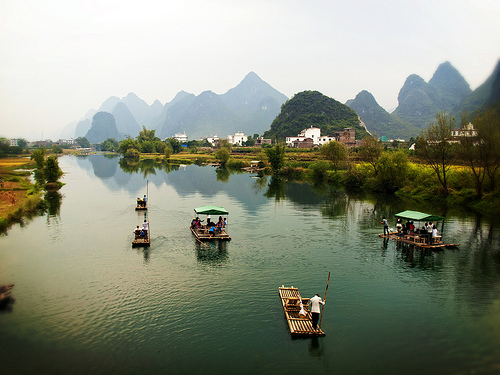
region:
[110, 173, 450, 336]
rafts on the river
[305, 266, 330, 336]
a person standing on a wooden raft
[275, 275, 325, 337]
a long bamboo raft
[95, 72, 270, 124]
pointed mountain peaks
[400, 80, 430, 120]
trees on a mountain side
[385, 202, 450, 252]
a raft with a green canopy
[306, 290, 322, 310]
a person wearing a white shirt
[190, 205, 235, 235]
people under a green canopy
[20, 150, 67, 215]
vegetation beside a river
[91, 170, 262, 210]
mountains reflecting in the water surface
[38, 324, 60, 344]
dark spot in water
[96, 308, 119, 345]
dark spot in water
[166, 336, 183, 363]
dark spot in water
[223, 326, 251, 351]
dark spot in water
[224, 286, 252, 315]
dark spot in water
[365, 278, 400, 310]
dark spot in water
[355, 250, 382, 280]
dark spot in water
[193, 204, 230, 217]
a green cover over a boat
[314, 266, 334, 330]
a long pole in a man's hand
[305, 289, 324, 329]
a man on a raft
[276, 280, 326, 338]
a raft on a river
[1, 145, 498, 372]
a beautiful green river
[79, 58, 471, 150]
small mountains in the distance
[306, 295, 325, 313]
a white shirt on a man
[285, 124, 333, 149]
a white building in front of a hill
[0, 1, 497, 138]
a foggy gray sky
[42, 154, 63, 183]
a green leafy tree next to the river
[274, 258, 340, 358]
Small boat in the water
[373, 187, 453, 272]
Small boat in the water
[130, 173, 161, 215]
Small boat in the water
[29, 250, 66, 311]
Small ripples in the water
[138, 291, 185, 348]
Small ripples in the water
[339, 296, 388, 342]
Small ripples in the water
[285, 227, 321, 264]
Small ripples in the water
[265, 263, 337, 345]
wooden raft in body of water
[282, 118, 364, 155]
buildings beyond grass plain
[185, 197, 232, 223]
green roof on wooden raft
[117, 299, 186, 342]
dark ripples on surface of water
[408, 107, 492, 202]
trees bordering body of water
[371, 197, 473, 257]
people standing on wooden raft in water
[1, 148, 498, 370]
large body of water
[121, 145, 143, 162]
short green bush on edge of water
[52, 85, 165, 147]
reflection and shadow of mountains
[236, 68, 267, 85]
peak at mountain top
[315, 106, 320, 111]
A green leaf on a plant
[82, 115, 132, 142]
a mountain peak by the water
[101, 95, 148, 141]
mountain peak by the water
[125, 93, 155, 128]
mountain peak by the water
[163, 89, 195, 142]
mountain peak by the water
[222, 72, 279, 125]
mountain peak by the water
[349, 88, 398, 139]
mountain peak by the water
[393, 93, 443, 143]
mountain peak by the water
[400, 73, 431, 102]
mountain peak by the water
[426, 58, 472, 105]
mountain peak by the water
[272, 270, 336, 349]
The man in the back on his raft.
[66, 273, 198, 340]
The green wavy water.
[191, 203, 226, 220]
The green covering on the raft.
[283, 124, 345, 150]
A group of houses.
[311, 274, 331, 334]
A man holding a stick.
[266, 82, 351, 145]
The large mountain of nature.